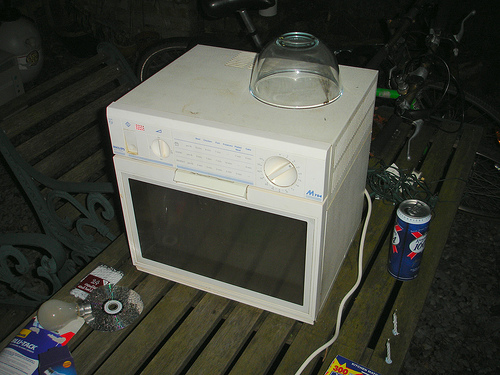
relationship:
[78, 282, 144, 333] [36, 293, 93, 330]
cd under bulb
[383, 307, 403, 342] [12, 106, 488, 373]
candle attached to table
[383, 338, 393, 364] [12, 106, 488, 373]
candle attached to table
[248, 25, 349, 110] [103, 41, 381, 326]
bowl sitting on microwave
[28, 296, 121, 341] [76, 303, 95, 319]
light with base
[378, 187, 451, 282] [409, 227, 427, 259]
can with design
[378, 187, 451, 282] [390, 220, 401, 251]
can with design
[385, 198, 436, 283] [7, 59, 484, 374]
can on table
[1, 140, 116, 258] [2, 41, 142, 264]
arm rest on chair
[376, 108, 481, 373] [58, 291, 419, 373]
slat on table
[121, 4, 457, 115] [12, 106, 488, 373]
bicycle behind table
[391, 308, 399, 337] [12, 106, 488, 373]
candle on table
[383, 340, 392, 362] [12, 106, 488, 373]
candle on table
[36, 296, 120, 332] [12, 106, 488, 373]
light on table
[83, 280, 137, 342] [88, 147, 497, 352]
cd on table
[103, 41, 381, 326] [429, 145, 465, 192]
microwave on bench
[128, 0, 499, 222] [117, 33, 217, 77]
bicycle has wheel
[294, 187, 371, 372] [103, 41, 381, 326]
cord of microwave